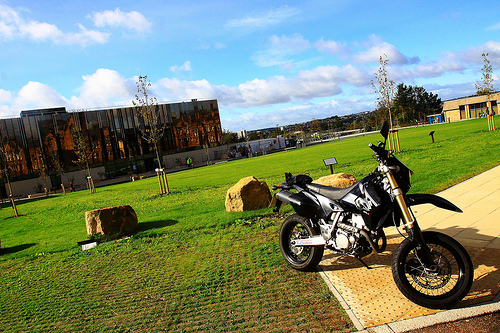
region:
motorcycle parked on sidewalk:
[264, 119, 474, 309]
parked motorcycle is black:
[270, 105, 475, 311]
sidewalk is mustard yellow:
[303, 142, 498, 328]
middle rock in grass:
[216, 170, 273, 218]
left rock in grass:
[76, 197, 141, 247]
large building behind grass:
[0, 83, 290, 212]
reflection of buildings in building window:
[4, 101, 218, 183]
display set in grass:
[427, 125, 439, 143]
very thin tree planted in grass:
[125, 73, 180, 204]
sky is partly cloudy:
[1, 2, 499, 142]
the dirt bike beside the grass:
[254, 103, 476, 322]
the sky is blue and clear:
[376, 8, 482, 36]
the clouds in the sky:
[225, 68, 351, 109]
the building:
[5, 94, 232, 181]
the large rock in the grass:
[63, 196, 160, 244]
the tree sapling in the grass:
[117, 60, 189, 197]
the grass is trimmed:
[182, 137, 295, 203]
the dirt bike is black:
[243, 118, 498, 307]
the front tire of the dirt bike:
[359, 215, 474, 326]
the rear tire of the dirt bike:
[262, 205, 343, 283]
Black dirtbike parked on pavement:
[264, 153, 469, 317]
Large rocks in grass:
[75, 194, 152, 234]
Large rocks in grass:
[220, 176, 271, 236]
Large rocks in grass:
[308, 162, 366, 192]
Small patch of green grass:
[245, 294, 295, 327]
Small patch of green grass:
[159, 279, 207, 316]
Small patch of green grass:
[70, 263, 150, 320]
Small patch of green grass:
[175, 216, 219, 262]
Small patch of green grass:
[183, 190, 227, 237]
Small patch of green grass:
[277, 139, 329, 169]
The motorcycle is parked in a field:
[211, 122, 496, 328]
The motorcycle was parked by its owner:
[225, 85, 483, 330]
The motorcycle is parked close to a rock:
[216, 135, 488, 330]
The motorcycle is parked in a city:
[205, 140, 496, 320]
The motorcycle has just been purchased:
[196, 117, 492, 322]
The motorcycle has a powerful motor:
[216, 123, 483, 329]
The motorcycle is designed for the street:
[230, 112, 490, 322]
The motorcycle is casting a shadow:
[240, 125, 498, 330]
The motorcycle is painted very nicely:
[225, 132, 490, 328]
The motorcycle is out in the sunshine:
[225, 3, 496, 327]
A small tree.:
[127, 75, 172, 195]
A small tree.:
[67, 121, 97, 193]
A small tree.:
[0, 122, 22, 219]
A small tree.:
[368, 52, 398, 133]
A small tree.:
[473, 51, 495, 117]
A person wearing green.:
[186, 157, 194, 169]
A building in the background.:
[0, 99, 222, 207]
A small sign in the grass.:
[323, 157, 336, 174]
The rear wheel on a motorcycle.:
[276, 214, 323, 271]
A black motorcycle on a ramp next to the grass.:
[268, 121, 473, 309]